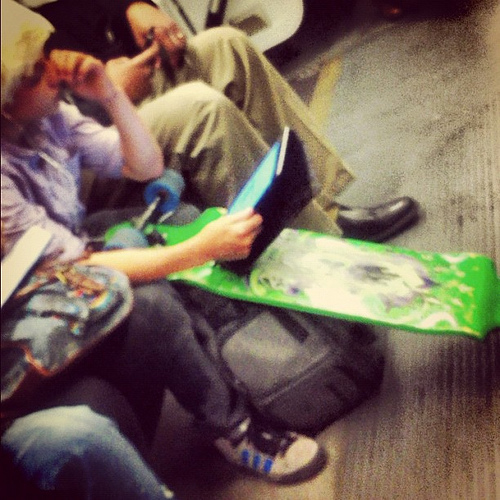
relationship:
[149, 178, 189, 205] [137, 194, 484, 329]
wheels are on skateboard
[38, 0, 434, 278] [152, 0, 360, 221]
man wearing pants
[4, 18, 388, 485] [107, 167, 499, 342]
boy holding skateboard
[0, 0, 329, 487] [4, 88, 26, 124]
boy wearing earphones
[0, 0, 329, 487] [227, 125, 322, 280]
boy looking at a computer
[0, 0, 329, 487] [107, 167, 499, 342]
boy has skateboard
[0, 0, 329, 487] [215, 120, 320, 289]
boy has tablet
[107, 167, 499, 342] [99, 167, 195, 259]
skateboard has wheels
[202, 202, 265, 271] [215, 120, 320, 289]
hand holds tablet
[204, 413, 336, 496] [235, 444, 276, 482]
shoe has stripes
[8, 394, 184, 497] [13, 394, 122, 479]
pants has knee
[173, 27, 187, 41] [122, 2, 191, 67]
ring on hand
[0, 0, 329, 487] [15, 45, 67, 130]
boy has face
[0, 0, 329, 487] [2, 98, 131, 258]
boy has shirt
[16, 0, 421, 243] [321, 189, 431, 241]
man wears shoes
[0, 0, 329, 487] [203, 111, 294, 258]
boy using computer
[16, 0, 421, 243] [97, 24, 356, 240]
man wears pants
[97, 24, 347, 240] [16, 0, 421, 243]
pants on a man